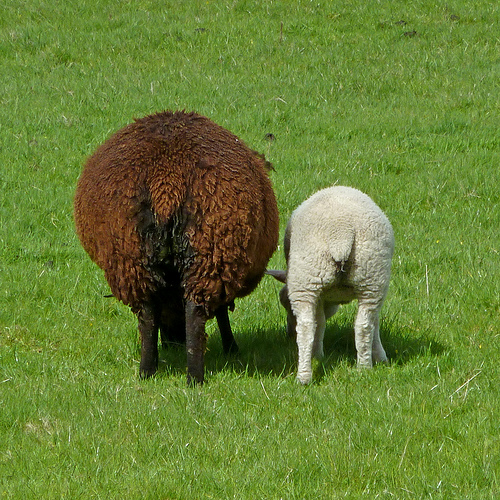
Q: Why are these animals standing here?
A: They are grazing.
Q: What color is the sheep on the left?
A: Brown.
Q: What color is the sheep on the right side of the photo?
A: White.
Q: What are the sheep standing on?
A: Grass.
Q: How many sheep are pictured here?
A: Two.